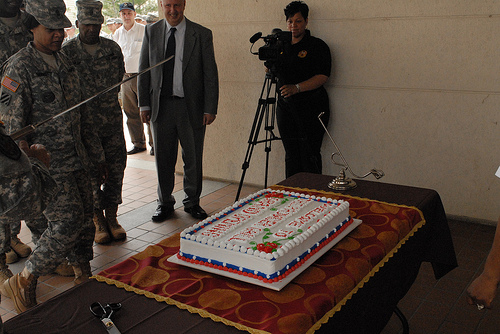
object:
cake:
[176, 186, 356, 283]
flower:
[254, 240, 276, 255]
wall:
[171, 0, 500, 221]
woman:
[259, 1, 334, 180]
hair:
[281, 0, 311, 18]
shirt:
[268, 31, 333, 105]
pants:
[274, 88, 330, 176]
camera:
[250, 27, 316, 100]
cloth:
[92, 182, 430, 332]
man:
[134, 0, 218, 224]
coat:
[134, 18, 219, 118]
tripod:
[229, 72, 318, 201]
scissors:
[83, 295, 125, 332]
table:
[0, 162, 500, 332]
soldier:
[63, 0, 129, 245]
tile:
[127, 229, 150, 248]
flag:
[2, 75, 20, 93]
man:
[112, 2, 155, 155]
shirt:
[113, 24, 149, 75]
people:
[61, 12, 162, 42]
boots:
[90, 213, 130, 244]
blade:
[10, 55, 179, 139]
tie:
[159, 27, 177, 101]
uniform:
[62, 38, 127, 214]